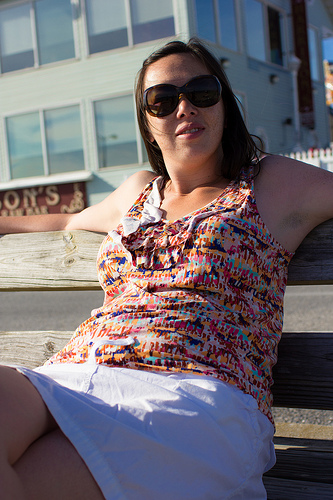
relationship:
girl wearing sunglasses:
[1, 34, 332, 498] [140, 72, 225, 118]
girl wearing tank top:
[1, 34, 332, 498] [41, 151, 298, 427]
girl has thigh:
[1, 34, 332, 498] [0, 387, 105, 499]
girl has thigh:
[1, 34, 332, 498] [13, 427, 105, 499]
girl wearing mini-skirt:
[1, 34, 332, 498] [15, 360, 277, 500]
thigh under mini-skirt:
[0, 387, 105, 499] [15, 360, 277, 500]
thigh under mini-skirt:
[13, 427, 105, 499] [15, 360, 277, 500]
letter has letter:
[3, 185, 61, 213] [3, 189, 19, 210]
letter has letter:
[3, 185, 61, 213] [24, 188, 37, 209]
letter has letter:
[3, 185, 61, 213] [45, 185, 59, 204]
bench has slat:
[1, 218, 332, 500] [0, 220, 332, 291]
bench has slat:
[1, 218, 332, 500] [1, 330, 332, 408]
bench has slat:
[1, 218, 332, 500] [263, 421, 332, 484]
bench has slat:
[1, 218, 332, 500] [260, 475, 332, 500]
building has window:
[0, 0, 332, 206] [1, 0, 76, 75]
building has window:
[0, 0, 332, 206] [84, 2, 177, 55]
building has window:
[0, 0, 332, 206] [4, 104, 86, 179]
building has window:
[0, 0, 332, 206] [93, 93, 151, 172]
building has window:
[0, 0, 332, 206] [195, 0, 242, 53]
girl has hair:
[1, 34, 332, 498] [134, 37, 265, 182]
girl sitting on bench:
[1, 34, 332, 498] [1, 218, 332, 500]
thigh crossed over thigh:
[0, 387, 105, 499] [13, 427, 105, 499]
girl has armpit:
[1, 34, 332, 498] [282, 209, 311, 229]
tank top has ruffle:
[41, 151, 298, 427] [109, 173, 250, 270]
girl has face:
[1, 34, 332, 498] [142, 52, 226, 165]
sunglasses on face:
[140, 72, 225, 118] [142, 52, 226, 165]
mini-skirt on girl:
[15, 360, 277, 500] [1, 34, 332, 498]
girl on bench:
[1, 34, 332, 498] [1, 218, 332, 500]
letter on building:
[3, 185, 61, 213] [0, 0, 332, 206]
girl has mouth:
[1, 34, 332, 498] [175, 121, 207, 140]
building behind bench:
[0, 0, 332, 206] [1, 218, 332, 500]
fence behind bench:
[276, 147, 332, 171] [1, 218, 332, 500]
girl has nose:
[1, 34, 332, 498] [176, 91, 199, 119]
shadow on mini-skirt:
[20, 369, 279, 500] [15, 360, 277, 500]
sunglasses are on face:
[140, 72, 225, 118] [142, 52, 226, 165]